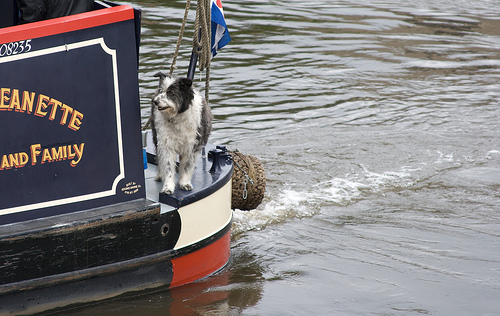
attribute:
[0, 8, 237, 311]
boat — black , white , red , blue 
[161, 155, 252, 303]
front — white 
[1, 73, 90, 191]
gold writing — Gold 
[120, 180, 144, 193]
small writing — Small 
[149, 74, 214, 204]
scruffy dog — Grey , white , scruffy 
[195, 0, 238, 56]
flag — Red, white, blue 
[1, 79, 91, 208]
yellow writing — Yellow 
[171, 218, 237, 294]
bottom — Red 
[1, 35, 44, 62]
white numbers — White 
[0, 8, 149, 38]
red trim — Red 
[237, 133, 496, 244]
bubbley wake — Bubbley 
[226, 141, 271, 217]
hanging items — brown, basket-like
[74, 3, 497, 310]
water — still, murky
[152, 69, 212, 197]
dog — black, white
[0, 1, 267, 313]
boat — blue , orange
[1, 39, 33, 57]
letters — white